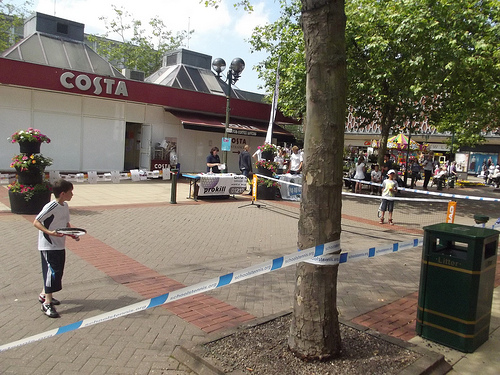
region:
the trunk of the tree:
[296, 10, 338, 338]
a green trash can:
[419, 218, 489, 335]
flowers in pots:
[10, 128, 56, 198]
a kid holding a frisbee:
[35, 185, 89, 319]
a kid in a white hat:
[371, 165, 407, 219]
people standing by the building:
[326, 135, 493, 177]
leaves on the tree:
[360, 33, 468, 93]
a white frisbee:
[55, 222, 87, 237]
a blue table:
[183, 168, 265, 202]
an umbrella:
[373, 133, 429, 150]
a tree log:
[301, 127, 347, 239]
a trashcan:
[426, 224, 478, 344]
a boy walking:
[40, 182, 92, 320]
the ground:
[140, 208, 196, 250]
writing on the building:
[59, 71, 134, 101]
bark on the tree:
[306, 144, 334, 195]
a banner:
[196, 177, 248, 199]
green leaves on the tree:
[396, 24, 463, 86]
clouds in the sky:
[236, 18, 256, 37]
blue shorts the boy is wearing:
[38, 249, 71, 291]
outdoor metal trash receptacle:
[417, 221, 499, 351]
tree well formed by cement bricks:
[171, 303, 444, 372]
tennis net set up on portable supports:
[238, 172, 455, 223]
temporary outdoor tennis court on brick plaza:
[2, 172, 498, 356]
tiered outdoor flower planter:
[11, 126, 54, 215]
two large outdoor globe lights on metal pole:
[210, 56, 245, 171]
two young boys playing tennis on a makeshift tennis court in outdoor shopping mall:
[0, 168, 497, 349]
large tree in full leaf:
[252, 0, 497, 165]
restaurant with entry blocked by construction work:
[0, 10, 300, 176]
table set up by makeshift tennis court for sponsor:
[181, 147, 248, 202]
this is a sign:
[56, 70, 133, 100]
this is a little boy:
[23, 178, 88, 321]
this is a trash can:
[412, 220, 499, 355]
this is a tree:
[283, 0, 350, 364]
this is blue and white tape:
[4, 220, 498, 363]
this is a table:
[179, 169, 250, 204]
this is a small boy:
[375, 167, 401, 227]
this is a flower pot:
[4, 124, 57, 215]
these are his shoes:
[39, 292, 61, 320]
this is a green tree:
[245, 0, 498, 189]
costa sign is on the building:
[46, 57, 138, 112]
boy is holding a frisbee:
[23, 170, 94, 330]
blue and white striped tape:
[58, 266, 322, 336]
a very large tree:
[347, 8, 467, 194]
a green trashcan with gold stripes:
[409, 207, 499, 350]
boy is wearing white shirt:
[26, 170, 96, 255]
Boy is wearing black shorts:
[30, 237, 91, 301]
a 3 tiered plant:
[3, 118, 58, 230]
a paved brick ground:
[133, 200, 257, 305]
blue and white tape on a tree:
[269, 222, 360, 289]